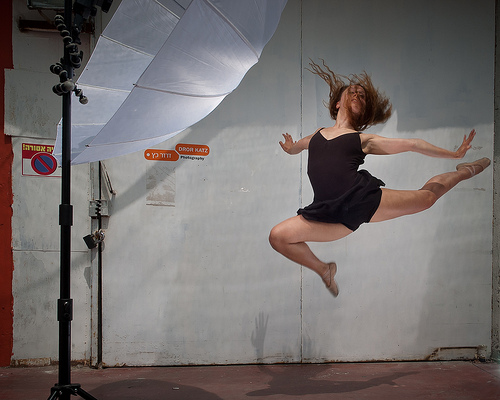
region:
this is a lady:
[245, 63, 490, 291]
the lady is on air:
[250, 73, 487, 292]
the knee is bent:
[259, 215, 311, 286]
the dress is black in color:
[310, 145, 356, 207]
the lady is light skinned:
[283, 223, 307, 237]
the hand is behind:
[394, 122, 486, 156]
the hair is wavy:
[368, 85, 383, 120]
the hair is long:
[368, 81, 385, 123]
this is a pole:
[55, 84, 88, 395]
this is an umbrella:
[107, 22, 217, 96]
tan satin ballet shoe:
[456, 149, 497, 176]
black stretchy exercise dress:
[298, 120, 388, 232]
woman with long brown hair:
[294, 52, 414, 128]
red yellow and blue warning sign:
[11, 136, 79, 185]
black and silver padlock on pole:
[79, 226, 116, 254]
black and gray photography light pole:
[36, 1, 102, 398]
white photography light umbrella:
[53, 0, 288, 150]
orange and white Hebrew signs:
[141, 140, 219, 165]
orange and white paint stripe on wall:
[0, 0, 20, 367]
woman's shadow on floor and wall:
[242, 313, 424, 398]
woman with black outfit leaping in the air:
[263, 51, 488, 300]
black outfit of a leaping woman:
[296, 126, 383, 231]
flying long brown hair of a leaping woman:
[300, 57, 397, 134]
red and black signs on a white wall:
[134, 134, 219, 214]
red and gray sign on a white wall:
[8, 136, 59, 186]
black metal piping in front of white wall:
[37, 19, 96, 396]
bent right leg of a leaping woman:
[266, 208, 353, 297]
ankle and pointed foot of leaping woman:
[448, 151, 490, 187]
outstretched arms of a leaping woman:
[271, 123, 482, 164]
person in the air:
[273, 72, 486, 317]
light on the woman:
[106, 0, 249, 158]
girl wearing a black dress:
[300, 123, 370, 238]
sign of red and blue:
[15, 136, 58, 182]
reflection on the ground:
[234, 315, 369, 397]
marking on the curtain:
[408, 325, 490, 373]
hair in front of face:
[318, 67, 390, 129]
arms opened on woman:
[290, 131, 484, 162]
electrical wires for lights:
[47, 0, 90, 112]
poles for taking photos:
[79, 148, 105, 370]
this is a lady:
[258, 65, 485, 301]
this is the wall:
[205, 165, 263, 312]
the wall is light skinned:
[193, 211, 238, 308]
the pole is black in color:
[53, 120, 78, 186]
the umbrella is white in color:
[153, 34, 210, 101]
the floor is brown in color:
[308, 370, 371, 399]